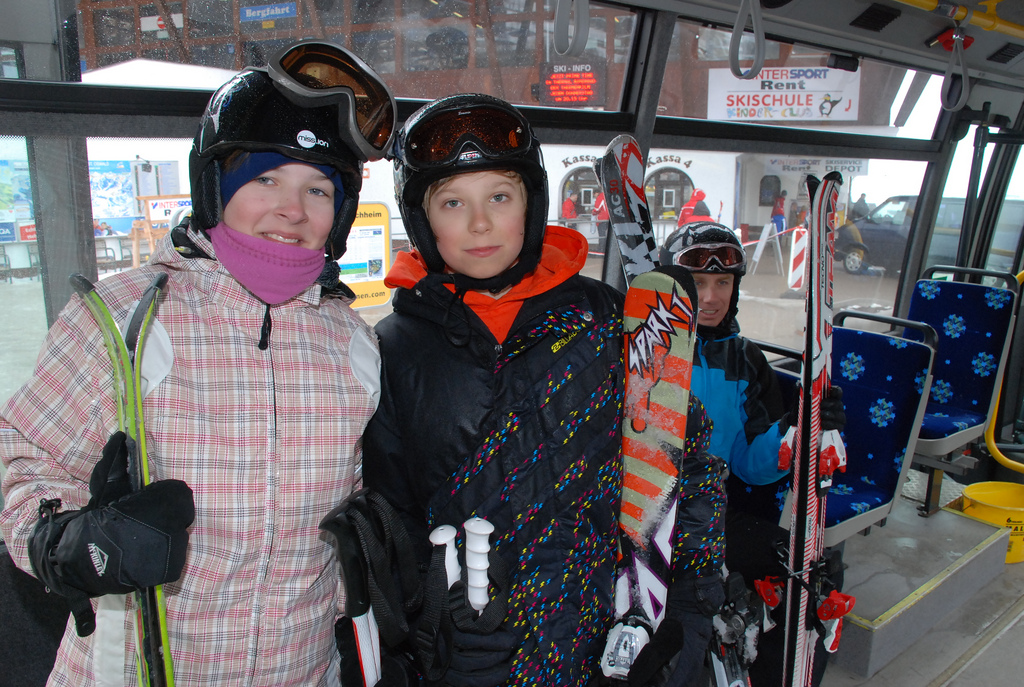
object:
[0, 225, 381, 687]
pink jacket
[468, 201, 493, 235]
woman nose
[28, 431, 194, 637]
mitten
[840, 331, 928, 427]
designs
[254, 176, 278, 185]
eye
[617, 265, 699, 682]
ski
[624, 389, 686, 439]
stripe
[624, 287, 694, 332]
stripe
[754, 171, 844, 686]
skis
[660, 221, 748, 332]
helmet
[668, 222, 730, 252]
light reflection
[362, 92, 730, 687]
person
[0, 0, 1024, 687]
bus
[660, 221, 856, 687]
person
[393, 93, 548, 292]
helmet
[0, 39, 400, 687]
person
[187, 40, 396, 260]
helmet